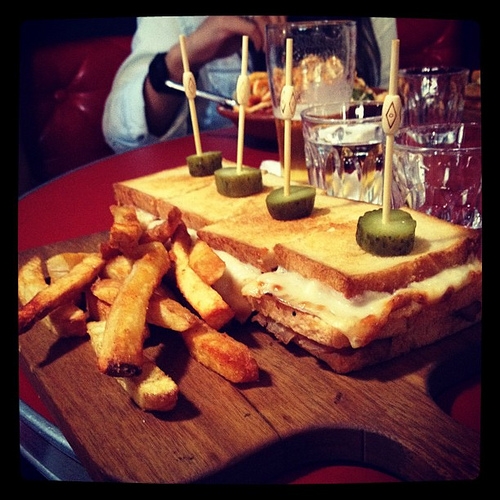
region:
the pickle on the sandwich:
[187, 152, 221, 176]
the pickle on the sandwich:
[212, 167, 261, 197]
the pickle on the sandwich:
[267, 184, 316, 219]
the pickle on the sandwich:
[356, 207, 416, 257]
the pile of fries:
[17, 201, 259, 413]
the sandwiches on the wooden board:
[112, 153, 484, 372]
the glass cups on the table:
[264, 21, 481, 228]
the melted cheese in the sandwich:
[241, 254, 481, 349]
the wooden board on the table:
[16, 227, 481, 483]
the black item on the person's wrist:
[147, 52, 182, 97]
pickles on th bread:
[182, 131, 410, 255]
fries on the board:
[47, 252, 239, 387]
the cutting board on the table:
[48, 246, 450, 478]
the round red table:
[36, 142, 471, 479]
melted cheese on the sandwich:
[139, 203, 451, 352]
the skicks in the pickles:
[157, 53, 435, 235]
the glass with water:
[300, 114, 393, 191]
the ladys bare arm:
[138, 37, 249, 123]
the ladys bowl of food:
[181, 77, 377, 137]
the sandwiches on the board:
[119, 169, 438, 371]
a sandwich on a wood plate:
[41, 55, 491, 407]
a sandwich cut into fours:
[87, 73, 488, 440]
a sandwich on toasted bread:
[62, 93, 495, 419]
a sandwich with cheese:
[62, 98, 497, 446]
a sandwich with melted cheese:
[80, 83, 499, 413]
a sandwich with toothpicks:
[90, 33, 460, 370]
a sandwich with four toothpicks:
[91, 77, 497, 399]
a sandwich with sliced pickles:
[142, 87, 444, 359]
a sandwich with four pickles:
[114, 98, 492, 346]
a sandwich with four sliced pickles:
[110, 87, 499, 394]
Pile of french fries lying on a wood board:
[17, 202, 261, 411]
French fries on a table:
[17, 200, 260, 414]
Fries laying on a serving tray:
[18, 202, 263, 415]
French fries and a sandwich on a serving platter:
[18, 31, 483, 413]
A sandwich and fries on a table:
[18, 30, 483, 411]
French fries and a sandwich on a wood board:
[21, 31, 478, 413]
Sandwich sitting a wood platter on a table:
[111, 30, 481, 377]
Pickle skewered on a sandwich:
[354, 202, 419, 258]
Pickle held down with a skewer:
[353, 35, 418, 258]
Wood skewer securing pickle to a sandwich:
[354, 37, 418, 259]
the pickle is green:
[356, 202, 418, 255]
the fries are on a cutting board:
[19, 197, 267, 423]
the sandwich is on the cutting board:
[246, 233, 478, 376]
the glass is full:
[297, 102, 389, 194]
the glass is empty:
[403, 134, 485, 224]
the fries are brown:
[15, 200, 265, 423]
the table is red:
[48, 191, 95, 220]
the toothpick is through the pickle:
[370, 86, 413, 217]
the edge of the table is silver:
[23, 415, 59, 480]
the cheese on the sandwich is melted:
[205, 187, 482, 368]